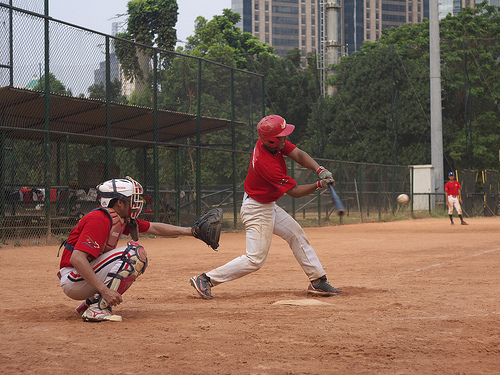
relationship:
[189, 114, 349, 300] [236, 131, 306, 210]
baseball players wears red shirt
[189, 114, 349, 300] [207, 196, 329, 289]
baseball players wears grey slacks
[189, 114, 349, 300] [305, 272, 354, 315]
baseball players wears black shoes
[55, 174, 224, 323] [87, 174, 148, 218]
catcher wears white helmet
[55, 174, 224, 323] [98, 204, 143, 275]
catcher wears chest guard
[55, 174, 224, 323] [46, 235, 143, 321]
catcher wears white pants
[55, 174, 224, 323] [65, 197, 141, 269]
catcher wears red shirt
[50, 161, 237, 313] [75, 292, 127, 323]
catcher wears white shoes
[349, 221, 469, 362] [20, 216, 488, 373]
dirt on field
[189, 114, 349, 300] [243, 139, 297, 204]
baseball players in red shirt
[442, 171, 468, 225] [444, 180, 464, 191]
man in shirt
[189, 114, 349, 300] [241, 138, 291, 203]
baseball players in shirt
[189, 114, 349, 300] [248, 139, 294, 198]
baseball players in shirt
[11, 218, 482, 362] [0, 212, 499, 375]
dirt on field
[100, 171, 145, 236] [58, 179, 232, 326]
mask of catcher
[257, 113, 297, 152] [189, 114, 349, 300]
helmet of baseball players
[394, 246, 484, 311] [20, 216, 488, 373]
lines on field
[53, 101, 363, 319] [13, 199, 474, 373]
baseball players on field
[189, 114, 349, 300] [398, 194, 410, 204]
baseball players hitting ball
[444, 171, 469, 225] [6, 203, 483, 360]
man out in field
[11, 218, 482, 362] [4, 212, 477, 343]
dirt on field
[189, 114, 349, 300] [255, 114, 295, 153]
baseball players wearing helmet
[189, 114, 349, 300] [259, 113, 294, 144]
baseball players wearing helmet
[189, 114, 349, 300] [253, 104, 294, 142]
baseball players wearing helmet